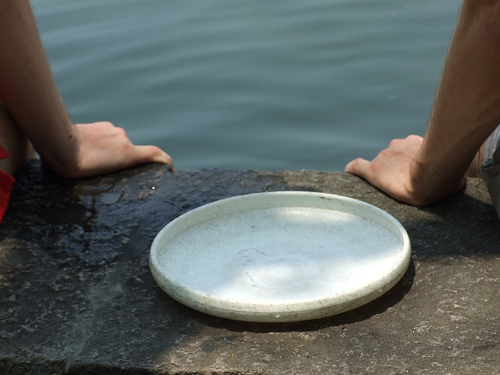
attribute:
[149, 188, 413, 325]
frisbee — white, upside down, disk, worn out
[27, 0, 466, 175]
water — calm, dark, rippled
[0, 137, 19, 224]
shorts — red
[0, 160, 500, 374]
wall — concrete, stone, dry, wet, rough stone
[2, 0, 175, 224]
man — sitting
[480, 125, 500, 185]
swimming trunks — gray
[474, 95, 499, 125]
vein — raised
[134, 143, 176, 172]
pinky finger — extended